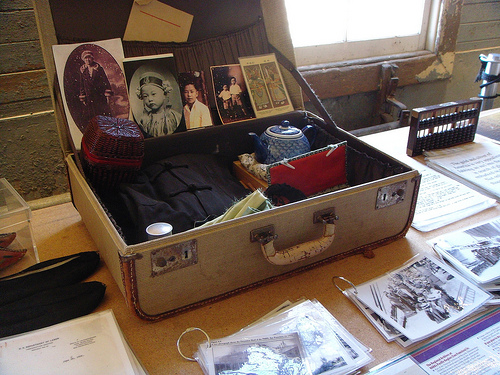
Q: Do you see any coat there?
A: Yes, there is a coat.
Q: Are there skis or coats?
A: Yes, there is a coat.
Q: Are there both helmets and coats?
A: No, there is a coat but no helmets.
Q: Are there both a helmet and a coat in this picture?
A: No, there is a coat but no helmets.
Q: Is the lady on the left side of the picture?
A: Yes, the lady is on the left of the image.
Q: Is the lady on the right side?
A: No, the lady is on the left of the image.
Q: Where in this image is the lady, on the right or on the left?
A: The lady is on the left of the image.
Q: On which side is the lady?
A: The lady is on the left of the image.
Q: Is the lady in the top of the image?
A: Yes, the lady is in the top of the image.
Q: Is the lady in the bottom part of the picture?
A: No, the lady is in the top of the image.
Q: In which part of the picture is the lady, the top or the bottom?
A: The lady is in the top of the image.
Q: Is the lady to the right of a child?
A: No, the lady is to the left of a child.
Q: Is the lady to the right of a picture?
A: No, the lady is to the left of a picture.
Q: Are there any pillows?
A: No, there are no pillows.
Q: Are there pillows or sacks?
A: No, there are no pillows or sacks.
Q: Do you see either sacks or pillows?
A: No, there are no pillows or sacks.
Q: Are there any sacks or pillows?
A: No, there are no pillows or sacks.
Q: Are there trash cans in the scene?
A: No, there are no trash cans.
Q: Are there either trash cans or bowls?
A: No, there are no trash cans or bowls.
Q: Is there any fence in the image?
A: No, there are no fences.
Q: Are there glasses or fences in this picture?
A: No, there are no fences or glasses.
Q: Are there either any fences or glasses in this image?
A: No, there are no fences or glasses.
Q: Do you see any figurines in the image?
A: No, there are no figurines.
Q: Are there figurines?
A: No, there are no figurines.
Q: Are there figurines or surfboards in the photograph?
A: No, there are no figurines or surfboards.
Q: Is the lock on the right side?
A: Yes, the lock is on the right of the image.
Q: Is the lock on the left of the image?
A: No, the lock is on the right of the image.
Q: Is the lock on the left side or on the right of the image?
A: The lock is on the right of the image.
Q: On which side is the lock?
A: The lock is on the right of the image.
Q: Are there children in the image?
A: Yes, there is a child.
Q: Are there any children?
A: Yes, there is a child.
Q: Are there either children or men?
A: Yes, there is a child.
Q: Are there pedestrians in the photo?
A: No, there are no pedestrians.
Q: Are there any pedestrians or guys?
A: No, there are no pedestrians or guys.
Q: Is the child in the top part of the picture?
A: Yes, the child is in the top of the image.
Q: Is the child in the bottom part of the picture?
A: No, the child is in the top of the image.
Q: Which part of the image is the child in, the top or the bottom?
A: The child is in the top of the image.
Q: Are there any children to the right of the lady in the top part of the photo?
A: Yes, there is a child to the right of the lady.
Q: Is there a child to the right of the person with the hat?
A: Yes, there is a child to the right of the lady.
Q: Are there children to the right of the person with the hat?
A: Yes, there is a child to the right of the lady.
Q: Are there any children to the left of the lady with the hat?
A: No, the child is to the right of the lady.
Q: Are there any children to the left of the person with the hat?
A: No, the child is to the right of the lady.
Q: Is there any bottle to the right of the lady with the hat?
A: No, there is a child to the right of the lady.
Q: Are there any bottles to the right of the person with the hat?
A: No, there is a child to the right of the lady.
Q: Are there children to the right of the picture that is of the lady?
A: Yes, there is a child to the right of the picture.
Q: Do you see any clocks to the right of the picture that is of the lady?
A: No, there is a child to the right of the picture.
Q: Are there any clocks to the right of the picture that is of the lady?
A: No, there is a child to the right of the picture.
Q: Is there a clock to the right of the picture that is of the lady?
A: No, there is a child to the right of the picture.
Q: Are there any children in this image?
A: Yes, there is a child.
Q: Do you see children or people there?
A: Yes, there is a child.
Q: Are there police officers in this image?
A: No, there are no police officers.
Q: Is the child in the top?
A: Yes, the child is in the top of the image.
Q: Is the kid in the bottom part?
A: No, the kid is in the top of the image.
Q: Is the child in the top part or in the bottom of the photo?
A: The child is in the top of the image.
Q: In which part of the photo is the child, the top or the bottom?
A: The child is in the top of the image.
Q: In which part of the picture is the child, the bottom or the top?
A: The child is in the top of the image.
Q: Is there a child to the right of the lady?
A: Yes, there is a child to the right of the lady.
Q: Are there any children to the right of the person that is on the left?
A: Yes, there is a child to the right of the lady.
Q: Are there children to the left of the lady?
A: No, the child is to the right of the lady.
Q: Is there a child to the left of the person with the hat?
A: No, the child is to the right of the lady.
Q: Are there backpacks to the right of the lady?
A: No, there is a child to the right of the lady.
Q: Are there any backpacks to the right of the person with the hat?
A: No, there is a child to the right of the lady.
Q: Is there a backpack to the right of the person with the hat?
A: No, there is a child to the right of the lady.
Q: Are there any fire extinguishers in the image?
A: No, there are no fire extinguishers.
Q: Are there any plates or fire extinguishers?
A: No, there are no fire extinguishers or plates.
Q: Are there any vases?
A: No, there are no vases.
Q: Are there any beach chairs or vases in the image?
A: No, there are no vases or beach chairs.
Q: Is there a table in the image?
A: Yes, there is a table.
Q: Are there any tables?
A: Yes, there is a table.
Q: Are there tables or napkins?
A: Yes, there is a table.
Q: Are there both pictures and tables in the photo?
A: Yes, there are both a table and a picture.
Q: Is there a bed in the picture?
A: No, there are no beds.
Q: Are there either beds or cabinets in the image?
A: No, there are no beds or cabinets.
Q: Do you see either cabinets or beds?
A: No, there are no beds or cabinets.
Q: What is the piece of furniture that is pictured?
A: The piece of furniture is a table.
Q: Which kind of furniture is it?
A: The piece of furniture is a table.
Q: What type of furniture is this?
A: This is a table.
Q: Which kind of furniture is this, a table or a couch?
A: This is a table.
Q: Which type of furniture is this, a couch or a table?
A: This is a table.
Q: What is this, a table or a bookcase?
A: This is a table.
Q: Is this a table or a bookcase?
A: This is a table.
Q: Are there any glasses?
A: No, there are no glasses.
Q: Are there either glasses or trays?
A: No, there are no glasses or trays.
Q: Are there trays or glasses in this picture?
A: No, there are no glasses or trays.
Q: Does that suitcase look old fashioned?
A: Yes, the suitcase is old fashioned.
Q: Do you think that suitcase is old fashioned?
A: Yes, the suitcase is old fashioned.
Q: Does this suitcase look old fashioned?
A: Yes, the suitcase is old fashioned.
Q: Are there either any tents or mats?
A: No, there are no tents or mats.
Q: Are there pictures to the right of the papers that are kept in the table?
A: Yes, there is a picture to the right of the papers.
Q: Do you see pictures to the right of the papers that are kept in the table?
A: Yes, there is a picture to the right of the papers.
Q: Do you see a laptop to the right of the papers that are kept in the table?
A: No, there is a picture to the right of the papers.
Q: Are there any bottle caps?
A: No, there are no bottle caps.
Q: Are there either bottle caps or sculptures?
A: No, there are no bottle caps or sculptures.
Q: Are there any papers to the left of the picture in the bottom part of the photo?
A: Yes, there are papers to the left of the picture.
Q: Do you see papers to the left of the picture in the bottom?
A: Yes, there are papers to the left of the picture.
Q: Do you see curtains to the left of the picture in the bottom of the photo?
A: No, there are papers to the left of the picture.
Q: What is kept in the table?
A: The papers are kept in the table.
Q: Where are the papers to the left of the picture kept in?
A: The papers are kept in the table.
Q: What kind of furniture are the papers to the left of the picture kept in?
A: The papers are kept in the table.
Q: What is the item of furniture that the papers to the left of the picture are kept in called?
A: The piece of furniture is a table.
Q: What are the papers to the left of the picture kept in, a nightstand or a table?
A: The papers are kept in a table.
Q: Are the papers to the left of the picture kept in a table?
A: Yes, the papers are kept in a table.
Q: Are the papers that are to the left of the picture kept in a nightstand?
A: No, the papers are kept in a table.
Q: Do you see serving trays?
A: No, there are no serving trays.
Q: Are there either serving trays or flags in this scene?
A: No, there are no serving trays or flags.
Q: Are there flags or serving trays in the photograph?
A: No, there are no serving trays or flags.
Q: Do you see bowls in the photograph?
A: No, there are no bowls.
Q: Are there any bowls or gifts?
A: No, there are no bowls or gifts.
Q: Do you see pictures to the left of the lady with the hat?
A: No, the picture is to the right of the lady.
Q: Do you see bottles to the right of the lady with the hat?
A: No, there is a picture to the right of the lady.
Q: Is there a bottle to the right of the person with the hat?
A: No, there is a picture to the right of the lady.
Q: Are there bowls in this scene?
A: No, there are no bowls.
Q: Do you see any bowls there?
A: No, there are no bowls.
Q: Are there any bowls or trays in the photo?
A: No, there are no bowls or trays.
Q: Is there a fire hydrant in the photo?
A: No, there are no fire hydrants.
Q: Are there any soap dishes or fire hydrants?
A: No, there are no fire hydrants or soap dishes.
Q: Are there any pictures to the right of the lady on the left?
A: Yes, there is a picture to the right of the lady.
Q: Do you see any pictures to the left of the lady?
A: No, the picture is to the right of the lady.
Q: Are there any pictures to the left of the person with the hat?
A: No, the picture is to the right of the lady.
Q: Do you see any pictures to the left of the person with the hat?
A: No, the picture is to the right of the lady.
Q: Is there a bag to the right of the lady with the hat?
A: No, there is a picture to the right of the lady.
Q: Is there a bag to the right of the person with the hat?
A: No, there is a picture to the right of the lady.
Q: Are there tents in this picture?
A: No, there are no tents.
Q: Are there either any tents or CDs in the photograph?
A: No, there are no tents or cds.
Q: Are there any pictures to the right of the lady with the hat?
A: Yes, there is a picture to the right of the lady.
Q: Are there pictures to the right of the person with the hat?
A: Yes, there is a picture to the right of the lady.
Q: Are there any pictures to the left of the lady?
A: No, the picture is to the right of the lady.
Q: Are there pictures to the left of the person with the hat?
A: No, the picture is to the right of the lady.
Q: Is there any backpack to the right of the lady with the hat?
A: No, there is a picture to the right of the lady.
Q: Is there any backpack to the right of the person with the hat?
A: No, there is a picture to the right of the lady.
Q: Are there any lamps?
A: No, there are no lamps.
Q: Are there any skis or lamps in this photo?
A: No, there are no lamps or skis.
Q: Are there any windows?
A: Yes, there is a window.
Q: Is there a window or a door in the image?
A: Yes, there is a window.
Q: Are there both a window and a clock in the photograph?
A: No, there is a window but no clocks.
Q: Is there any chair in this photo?
A: No, there are no chairs.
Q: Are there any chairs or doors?
A: No, there are no chairs or doors.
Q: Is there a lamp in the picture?
A: No, there are no lamps.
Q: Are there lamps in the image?
A: No, there are no lamps.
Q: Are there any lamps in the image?
A: No, there are no lamps.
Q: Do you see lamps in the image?
A: No, there are no lamps.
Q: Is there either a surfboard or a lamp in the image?
A: No, there are no lamps or surfboards.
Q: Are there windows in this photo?
A: Yes, there is a window.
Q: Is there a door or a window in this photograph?
A: Yes, there is a window.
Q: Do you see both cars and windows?
A: No, there is a window but no cars.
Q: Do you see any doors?
A: No, there are no doors.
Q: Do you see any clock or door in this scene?
A: No, there are no doors or clocks.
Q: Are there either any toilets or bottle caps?
A: No, there are no bottle caps or toilets.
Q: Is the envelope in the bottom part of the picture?
A: No, the envelope is in the top of the image.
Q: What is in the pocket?
A: The envelope is in the pocket.